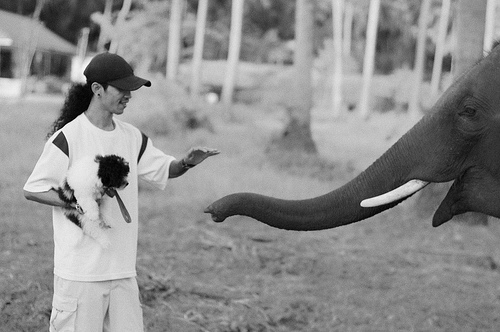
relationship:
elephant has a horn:
[204, 40, 499, 231] [360, 178, 431, 207]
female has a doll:
[23, 53, 222, 331] [59, 154, 131, 240]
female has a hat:
[23, 53, 222, 331] [85, 53, 152, 91]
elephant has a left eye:
[204, 40, 499, 231] [463, 107, 478, 116]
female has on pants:
[23, 53, 222, 331] [51, 276, 144, 331]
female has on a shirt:
[23, 53, 222, 331] [24, 109, 177, 282]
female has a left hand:
[23, 53, 222, 331] [183, 148, 219, 167]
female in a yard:
[23, 53, 222, 331] [4, 94, 500, 332]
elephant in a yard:
[204, 40, 499, 231] [4, 94, 500, 332]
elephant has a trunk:
[204, 40, 499, 231] [204, 117, 433, 230]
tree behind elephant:
[220, 2, 244, 119] [204, 40, 499, 231]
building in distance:
[1, 10, 80, 81] [0, 1, 499, 90]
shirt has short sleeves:
[24, 109, 177, 282] [25, 128, 69, 191]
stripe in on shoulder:
[54, 132, 69, 157] [48, 127, 81, 160]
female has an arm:
[23, 53, 222, 331] [142, 134, 219, 177]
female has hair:
[23, 53, 222, 331] [48, 82, 94, 136]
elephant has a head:
[204, 40, 499, 231] [433, 39, 500, 224]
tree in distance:
[220, 2, 244, 119] [0, 1, 499, 90]